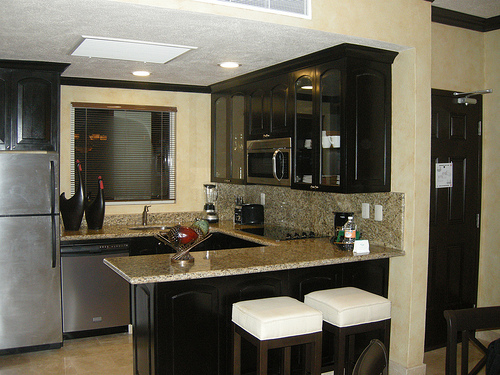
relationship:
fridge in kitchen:
[3, 151, 62, 357] [3, 0, 425, 370]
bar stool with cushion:
[231, 294, 326, 374] [230, 290, 321, 340]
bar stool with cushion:
[314, 285, 399, 374] [312, 280, 386, 330]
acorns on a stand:
[168, 219, 206, 244] [156, 228, 211, 270]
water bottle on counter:
[343, 213, 356, 245] [65, 215, 402, 285]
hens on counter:
[60, 148, 109, 232] [65, 215, 402, 285]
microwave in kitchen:
[245, 140, 286, 186] [3, 0, 425, 370]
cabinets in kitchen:
[202, 43, 390, 195] [3, 0, 425, 370]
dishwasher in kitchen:
[60, 240, 132, 339] [3, 0, 425, 370]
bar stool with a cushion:
[231, 294, 326, 374] [230, 290, 321, 340]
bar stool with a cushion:
[314, 285, 399, 374] [312, 280, 386, 330]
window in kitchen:
[75, 102, 177, 206] [3, 0, 425, 370]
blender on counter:
[199, 179, 222, 226] [65, 215, 402, 285]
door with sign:
[434, 89, 491, 356] [433, 157, 455, 192]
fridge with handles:
[3, 151, 62, 357] [48, 159, 61, 268]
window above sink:
[75, 102, 177, 206] [132, 224, 182, 240]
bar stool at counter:
[231, 294, 326, 374] [65, 215, 402, 285]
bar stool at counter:
[314, 285, 399, 374] [65, 215, 402, 285]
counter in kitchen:
[65, 215, 402, 285] [3, 0, 425, 370]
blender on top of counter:
[199, 179, 222, 226] [65, 215, 402, 285]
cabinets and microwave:
[202, 43, 390, 195] [245, 140, 286, 186]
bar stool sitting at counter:
[231, 294, 326, 374] [65, 215, 402, 285]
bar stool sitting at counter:
[314, 285, 399, 374] [65, 215, 402, 285]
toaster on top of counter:
[234, 202, 260, 225] [65, 215, 402, 285]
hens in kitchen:
[60, 148, 109, 232] [3, 0, 425, 370]